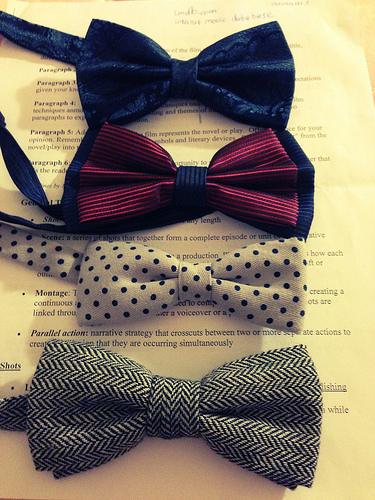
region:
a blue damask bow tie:
[79, 17, 293, 127]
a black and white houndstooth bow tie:
[29, 338, 323, 486]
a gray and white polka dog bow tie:
[0, 227, 305, 328]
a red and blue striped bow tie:
[0, 116, 319, 241]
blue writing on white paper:
[173, 4, 271, 25]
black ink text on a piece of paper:
[29, 326, 351, 350]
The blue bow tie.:
[1, 9, 314, 121]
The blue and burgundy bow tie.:
[2, 121, 322, 239]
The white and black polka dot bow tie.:
[2, 225, 308, 336]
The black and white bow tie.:
[4, 329, 323, 488]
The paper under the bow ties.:
[6, 1, 373, 498]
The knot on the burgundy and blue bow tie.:
[177, 166, 207, 194]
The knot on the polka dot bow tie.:
[175, 259, 218, 300]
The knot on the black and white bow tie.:
[146, 377, 201, 435]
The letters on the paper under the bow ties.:
[23, 23, 358, 437]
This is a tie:
[20, 325, 336, 499]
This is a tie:
[3, 235, 338, 346]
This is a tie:
[12, 115, 339, 239]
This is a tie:
[13, 1, 323, 127]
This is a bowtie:
[18, 228, 335, 353]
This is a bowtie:
[18, 6, 349, 130]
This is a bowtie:
[18, 327, 354, 493]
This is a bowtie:
[44, 230, 344, 340]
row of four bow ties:
[7, 14, 326, 490]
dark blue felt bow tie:
[68, 14, 303, 133]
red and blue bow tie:
[57, 111, 325, 243]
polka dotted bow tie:
[68, 232, 313, 334]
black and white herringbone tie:
[21, 334, 327, 494]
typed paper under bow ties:
[2, 4, 367, 438]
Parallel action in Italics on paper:
[28, 327, 86, 339]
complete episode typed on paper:
[188, 231, 250, 244]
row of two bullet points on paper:
[12, 287, 27, 338]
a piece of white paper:
[0, 0, 373, 499]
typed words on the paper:
[29, 328, 350, 348]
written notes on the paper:
[173, 5, 275, 24]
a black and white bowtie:
[0, 338, 322, 490]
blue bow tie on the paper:
[5, 3, 306, 123]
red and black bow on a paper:
[3, 106, 327, 233]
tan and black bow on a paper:
[5, 224, 318, 343]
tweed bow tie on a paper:
[14, 322, 356, 487]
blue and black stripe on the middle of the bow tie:
[174, 160, 206, 207]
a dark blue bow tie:
[5, 5, 325, 128]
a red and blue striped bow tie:
[11, 109, 343, 237]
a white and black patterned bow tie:
[21, 333, 367, 495]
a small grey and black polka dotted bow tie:
[9, 219, 339, 339]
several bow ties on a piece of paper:
[9, 5, 350, 491]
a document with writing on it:
[4, 6, 365, 490]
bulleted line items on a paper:
[15, 279, 354, 349]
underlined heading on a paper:
[0, 355, 32, 374]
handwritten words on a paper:
[166, 0, 351, 42]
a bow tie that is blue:
[67, 17, 309, 141]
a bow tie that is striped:
[91, 120, 313, 229]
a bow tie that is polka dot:
[84, 222, 307, 349]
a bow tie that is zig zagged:
[22, 327, 333, 497]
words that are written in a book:
[17, 288, 80, 328]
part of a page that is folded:
[307, 13, 373, 71]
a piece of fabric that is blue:
[11, 7, 68, 79]